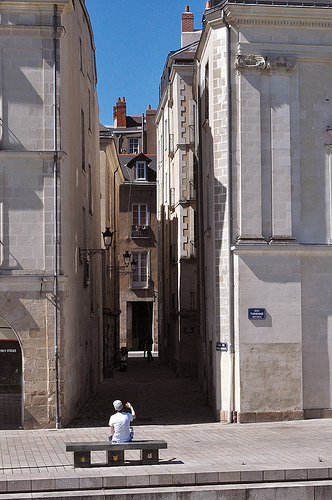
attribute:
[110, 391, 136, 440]
man — sitting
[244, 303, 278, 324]
poster — wall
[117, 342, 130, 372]
motorcycle — leaning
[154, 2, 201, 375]
building — brick, Tall 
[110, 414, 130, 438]
shirt — short sleeved, White 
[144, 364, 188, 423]
floor — part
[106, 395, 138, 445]
man — seated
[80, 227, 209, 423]
passage — long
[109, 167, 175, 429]
brown — color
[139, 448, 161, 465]
sand — part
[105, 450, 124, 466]
sand — part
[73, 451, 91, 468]
sand — part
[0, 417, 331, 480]
floor — part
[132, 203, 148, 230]
window — closed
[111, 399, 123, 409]
hat — white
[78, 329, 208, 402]
alley — narrow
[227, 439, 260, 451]
floor — part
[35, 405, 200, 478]
bench — edge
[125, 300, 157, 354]
doorway — arched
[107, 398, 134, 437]
person — standing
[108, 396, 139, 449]
person — watching, sitting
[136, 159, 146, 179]
window — long 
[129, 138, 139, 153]
window — long 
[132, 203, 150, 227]
window — long 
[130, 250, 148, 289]
window — long 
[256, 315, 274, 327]
shadow — long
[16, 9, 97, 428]
building — close, together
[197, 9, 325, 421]
building — close, together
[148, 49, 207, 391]
building — close, together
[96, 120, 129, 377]
building — close, together